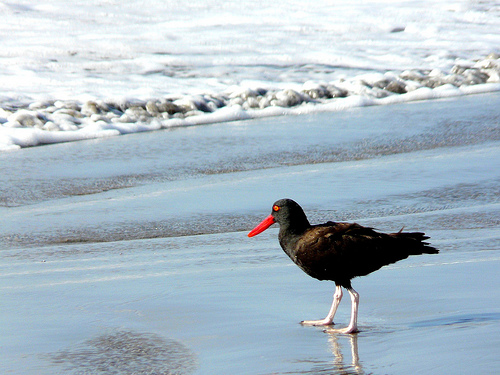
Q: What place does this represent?
A: It represents the beach.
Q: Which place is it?
A: It is a beach.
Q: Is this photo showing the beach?
A: Yes, it is showing the beach.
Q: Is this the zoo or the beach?
A: It is the beach.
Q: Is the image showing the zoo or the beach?
A: It is showing the beach.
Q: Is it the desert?
A: No, it is the beach.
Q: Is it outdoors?
A: Yes, it is outdoors.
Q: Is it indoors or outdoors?
A: It is outdoors.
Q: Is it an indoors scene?
A: No, it is outdoors.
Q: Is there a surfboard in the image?
A: No, there are no surfboards.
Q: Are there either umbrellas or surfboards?
A: No, there are no surfboards or umbrellas.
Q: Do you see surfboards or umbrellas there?
A: No, there are no surfboards or umbrellas.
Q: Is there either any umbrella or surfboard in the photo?
A: No, there are no surfboards or umbrellas.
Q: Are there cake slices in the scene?
A: No, there are no cake slices.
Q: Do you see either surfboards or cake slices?
A: No, there are no cake slices or surfboards.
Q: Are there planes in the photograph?
A: No, there are no planes.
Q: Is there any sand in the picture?
A: Yes, there is sand.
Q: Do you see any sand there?
A: Yes, there is sand.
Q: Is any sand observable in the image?
A: Yes, there is sand.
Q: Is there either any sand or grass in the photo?
A: Yes, there is sand.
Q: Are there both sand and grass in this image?
A: No, there is sand but no grass.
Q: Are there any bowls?
A: No, there are no bowls.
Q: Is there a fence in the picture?
A: No, there are no fences.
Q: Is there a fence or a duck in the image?
A: No, there are no fences or ducks.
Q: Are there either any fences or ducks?
A: No, there are no fences or ducks.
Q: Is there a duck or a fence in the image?
A: No, there are no fences or ducks.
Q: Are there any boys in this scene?
A: No, there are no boys.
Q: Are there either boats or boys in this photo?
A: No, there are no boys or boats.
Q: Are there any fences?
A: No, there are no fences.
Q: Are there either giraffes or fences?
A: No, there are no fences or giraffes.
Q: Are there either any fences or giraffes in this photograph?
A: No, there are no fences or giraffes.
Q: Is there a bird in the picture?
A: Yes, there is a bird.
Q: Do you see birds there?
A: Yes, there is a bird.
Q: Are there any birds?
A: Yes, there is a bird.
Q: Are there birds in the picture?
A: Yes, there is a bird.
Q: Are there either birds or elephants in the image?
A: Yes, there is a bird.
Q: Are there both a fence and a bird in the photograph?
A: No, there is a bird but no fences.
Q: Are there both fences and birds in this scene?
A: No, there is a bird but no fences.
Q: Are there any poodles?
A: No, there are no poodles.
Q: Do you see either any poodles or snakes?
A: No, there are no poodles or snakes.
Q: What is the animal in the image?
A: The animal is a bird.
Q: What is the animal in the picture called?
A: The animal is a bird.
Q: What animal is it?
A: The animal is a bird.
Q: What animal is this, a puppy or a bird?
A: That is a bird.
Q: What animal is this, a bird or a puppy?
A: That is a bird.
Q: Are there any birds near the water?
A: Yes, there is a bird near the water.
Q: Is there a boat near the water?
A: No, there is a bird near the water.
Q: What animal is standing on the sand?
A: The bird is standing on the sand.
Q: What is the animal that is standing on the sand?
A: The animal is a bird.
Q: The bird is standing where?
A: The bird is standing on the sand.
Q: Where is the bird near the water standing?
A: The bird is standing on the sand.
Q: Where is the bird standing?
A: The bird is standing on the sand.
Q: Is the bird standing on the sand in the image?
A: Yes, the bird is standing on the sand.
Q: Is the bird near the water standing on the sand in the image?
A: Yes, the bird is standing on the sand.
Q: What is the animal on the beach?
A: The animal is a bird.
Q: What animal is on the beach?
A: The animal is a bird.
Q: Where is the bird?
A: The bird is on the beach.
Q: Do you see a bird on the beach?
A: Yes, there is a bird on the beach.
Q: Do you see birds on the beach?
A: Yes, there is a bird on the beach.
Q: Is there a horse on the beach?
A: No, there is a bird on the beach.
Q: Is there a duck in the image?
A: No, there are no ducks.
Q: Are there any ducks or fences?
A: No, there are no ducks or fences.